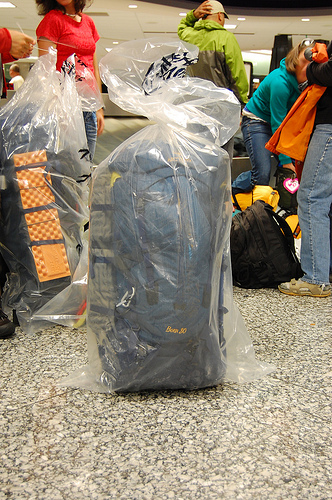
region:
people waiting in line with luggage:
[2, 1, 329, 401]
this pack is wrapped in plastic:
[79, 113, 239, 395]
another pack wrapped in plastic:
[1, 86, 93, 309]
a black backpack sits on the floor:
[230, 192, 304, 293]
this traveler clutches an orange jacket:
[261, 37, 330, 164]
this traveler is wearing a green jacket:
[176, 1, 252, 107]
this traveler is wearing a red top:
[35, 5, 103, 106]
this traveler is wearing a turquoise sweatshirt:
[239, 52, 307, 164]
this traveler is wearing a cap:
[199, 0, 232, 19]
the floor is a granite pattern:
[4, 397, 329, 498]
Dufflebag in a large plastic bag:
[52, 39, 273, 394]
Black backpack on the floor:
[229, 199, 304, 290]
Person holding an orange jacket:
[264, 36, 330, 297]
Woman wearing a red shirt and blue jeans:
[34, 0, 105, 163]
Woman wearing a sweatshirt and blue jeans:
[230, 34, 313, 195]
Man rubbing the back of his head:
[176, 0, 249, 167]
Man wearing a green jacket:
[177, 1, 248, 165]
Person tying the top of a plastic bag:
[0, 22, 78, 107]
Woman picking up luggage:
[230, 35, 312, 195]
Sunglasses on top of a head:
[297, 34, 315, 49]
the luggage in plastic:
[67, 114, 248, 384]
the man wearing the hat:
[180, 2, 253, 93]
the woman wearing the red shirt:
[27, 2, 119, 130]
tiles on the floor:
[5, 298, 330, 499]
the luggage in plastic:
[2, 69, 101, 313]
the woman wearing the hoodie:
[236, 48, 312, 141]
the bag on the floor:
[224, 191, 301, 284]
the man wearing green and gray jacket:
[181, 12, 250, 95]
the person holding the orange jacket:
[273, 54, 331, 166]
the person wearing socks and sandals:
[280, 272, 330, 301]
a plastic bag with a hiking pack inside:
[86, 41, 256, 401]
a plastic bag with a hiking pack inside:
[0, 72, 93, 319]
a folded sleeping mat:
[10, 149, 77, 291]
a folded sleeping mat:
[87, 163, 117, 337]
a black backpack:
[226, 199, 301, 291]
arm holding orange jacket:
[266, 35, 328, 166]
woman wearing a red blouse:
[34, 2, 113, 112]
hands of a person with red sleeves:
[1, 14, 35, 74]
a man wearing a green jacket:
[175, 3, 254, 103]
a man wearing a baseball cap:
[198, 0, 230, 32]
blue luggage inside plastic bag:
[67, 35, 277, 398]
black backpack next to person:
[231, 198, 306, 290]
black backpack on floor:
[226, 197, 308, 289]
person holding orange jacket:
[263, 21, 330, 297]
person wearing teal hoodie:
[232, 36, 311, 197]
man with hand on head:
[178, 1, 250, 166]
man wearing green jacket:
[178, 2, 250, 169]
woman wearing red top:
[32, 0, 103, 185]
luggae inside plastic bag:
[3, 52, 90, 336]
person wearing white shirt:
[8, 65, 24, 95]